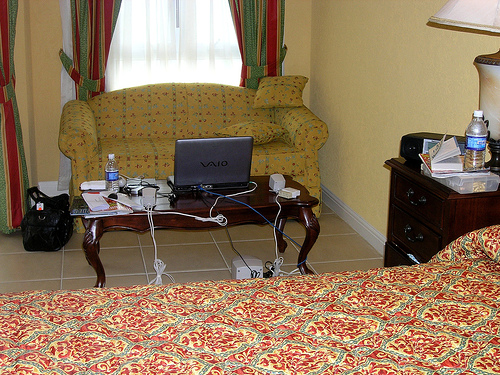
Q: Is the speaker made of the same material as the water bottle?
A: Yes, both the speaker and the water bottle are made of plastic.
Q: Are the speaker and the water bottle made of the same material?
A: Yes, both the speaker and the water bottle are made of plastic.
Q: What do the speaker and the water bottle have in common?
A: The material, both the speaker and the water bottle are plastic.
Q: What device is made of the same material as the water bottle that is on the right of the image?
A: The speaker is made of the same material as the water bottle.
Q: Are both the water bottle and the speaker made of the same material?
A: Yes, both the water bottle and the speaker are made of plastic.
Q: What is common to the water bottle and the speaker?
A: The material, both the water bottle and the speaker are plastic.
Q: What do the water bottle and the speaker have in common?
A: The material, both the water bottle and the speaker are plastic.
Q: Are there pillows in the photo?
A: Yes, there is a pillow.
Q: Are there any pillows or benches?
A: Yes, there is a pillow.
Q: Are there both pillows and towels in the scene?
A: No, there is a pillow but no towels.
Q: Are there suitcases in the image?
A: No, there are no suitcases.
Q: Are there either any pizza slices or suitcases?
A: No, there are no suitcases or pizza slices.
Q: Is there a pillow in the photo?
A: Yes, there is a pillow.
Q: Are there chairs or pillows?
A: Yes, there is a pillow.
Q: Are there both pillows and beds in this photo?
A: Yes, there are both a pillow and a bed.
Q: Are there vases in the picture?
A: No, there are no vases.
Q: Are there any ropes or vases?
A: No, there are no vases or ropes.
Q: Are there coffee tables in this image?
A: Yes, there is a coffee table.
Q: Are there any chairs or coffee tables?
A: Yes, there is a coffee table.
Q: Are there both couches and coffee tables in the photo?
A: Yes, there are both a coffee table and a couch.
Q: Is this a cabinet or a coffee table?
A: This is a coffee table.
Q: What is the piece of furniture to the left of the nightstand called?
A: The piece of furniture is a coffee table.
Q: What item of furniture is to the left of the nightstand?
A: The piece of furniture is a coffee table.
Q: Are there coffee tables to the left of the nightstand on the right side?
A: Yes, there is a coffee table to the left of the nightstand.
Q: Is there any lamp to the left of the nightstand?
A: No, there is a coffee table to the left of the nightstand.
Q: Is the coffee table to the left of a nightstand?
A: Yes, the coffee table is to the left of a nightstand.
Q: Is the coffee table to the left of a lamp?
A: No, the coffee table is to the left of a nightstand.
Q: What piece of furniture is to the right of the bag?
A: The piece of furniture is a coffee table.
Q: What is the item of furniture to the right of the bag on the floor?
A: The piece of furniture is a coffee table.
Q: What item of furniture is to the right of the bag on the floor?
A: The piece of furniture is a coffee table.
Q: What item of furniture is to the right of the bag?
A: The piece of furniture is a coffee table.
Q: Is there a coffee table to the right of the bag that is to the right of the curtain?
A: Yes, there is a coffee table to the right of the bag.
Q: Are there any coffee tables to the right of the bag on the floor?
A: Yes, there is a coffee table to the right of the bag.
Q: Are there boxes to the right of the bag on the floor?
A: No, there is a coffee table to the right of the bag.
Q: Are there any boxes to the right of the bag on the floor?
A: No, there is a coffee table to the right of the bag.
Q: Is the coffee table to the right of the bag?
A: Yes, the coffee table is to the right of the bag.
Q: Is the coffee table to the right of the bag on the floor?
A: Yes, the coffee table is to the right of the bag.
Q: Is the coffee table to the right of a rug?
A: No, the coffee table is to the right of the bag.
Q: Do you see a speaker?
A: Yes, there is a speaker.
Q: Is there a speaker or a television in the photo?
A: Yes, there is a speaker.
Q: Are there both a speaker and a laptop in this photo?
A: Yes, there are both a speaker and a laptop.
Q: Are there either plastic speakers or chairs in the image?
A: Yes, there is a plastic speaker.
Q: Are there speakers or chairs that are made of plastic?
A: Yes, the speaker is made of plastic.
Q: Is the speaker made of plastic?
A: Yes, the speaker is made of plastic.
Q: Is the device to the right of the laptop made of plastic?
A: Yes, the speaker is made of plastic.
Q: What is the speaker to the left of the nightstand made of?
A: The speaker is made of plastic.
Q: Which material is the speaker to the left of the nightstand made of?
A: The speaker is made of plastic.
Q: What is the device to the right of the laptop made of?
A: The speaker is made of plastic.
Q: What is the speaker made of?
A: The speaker is made of plastic.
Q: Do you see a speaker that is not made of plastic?
A: No, there is a speaker but it is made of plastic.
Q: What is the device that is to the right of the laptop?
A: The device is a speaker.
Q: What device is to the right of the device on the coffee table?
A: The device is a speaker.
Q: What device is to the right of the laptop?
A: The device is a speaker.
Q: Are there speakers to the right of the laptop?
A: Yes, there is a speaker to the right of the laptop.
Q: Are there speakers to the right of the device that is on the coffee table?
A: Yes, there is a speaker to the right of the laptop.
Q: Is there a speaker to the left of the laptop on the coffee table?
A: No, the speaker is to the right of the laptop.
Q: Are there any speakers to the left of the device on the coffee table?
A: No, the speaker is to the right of the laptop.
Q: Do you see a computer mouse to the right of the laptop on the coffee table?
A: No, there is a speaker to the right of the laptop.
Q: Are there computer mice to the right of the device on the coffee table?
A: No, there is a speaker to the right of the laptop.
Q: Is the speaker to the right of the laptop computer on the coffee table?
A: Yes, the speaker is to the right of the laptop computer.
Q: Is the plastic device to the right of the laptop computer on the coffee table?
A: Yes, the speaker is to the right of the laptop computer.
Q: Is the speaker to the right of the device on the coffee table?
A: Yes, the speaker is to the right of the laptop computer.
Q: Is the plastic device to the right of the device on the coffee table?
A: Yes, the speaker is to the right of the laptop computer.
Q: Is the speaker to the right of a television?
A: No, the speaker is to the right of the laptop computer.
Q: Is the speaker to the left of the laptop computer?
A: No, the speaker is to the right of the laptop computer.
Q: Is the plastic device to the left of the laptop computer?
A: No, the speaker is to the right of the laptop computer.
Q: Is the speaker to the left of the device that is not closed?
A: No, the speaker is to the right of the laptop computer.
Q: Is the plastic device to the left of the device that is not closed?
A: No, the speaker is to the right of the laptop computer.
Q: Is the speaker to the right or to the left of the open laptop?
A: The speaker is to the right of the laptop computer.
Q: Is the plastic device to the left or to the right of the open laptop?
A: The speaker is to the right of the laptop computer.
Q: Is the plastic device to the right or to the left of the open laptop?
A: The speaker is to the right of the laptop computer.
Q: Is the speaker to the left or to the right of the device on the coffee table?
A: The speaker is to the right of the laptop computer.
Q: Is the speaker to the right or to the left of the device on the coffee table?
A: The speaker is to the right of the laptop computer.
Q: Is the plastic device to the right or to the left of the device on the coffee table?
A: The speaker is to the right of the laptop computer.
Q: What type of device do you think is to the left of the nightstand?
A: The device is a speaker.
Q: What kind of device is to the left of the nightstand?
A: The device is a speaker.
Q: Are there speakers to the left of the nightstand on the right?
A: Yes, there is a speaker to the left of the nightstand.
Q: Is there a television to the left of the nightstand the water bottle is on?
A: No, there is a speaker to the left of the nightstand.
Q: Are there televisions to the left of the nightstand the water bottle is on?
A: No, there is a speaker to the left of the nightstand.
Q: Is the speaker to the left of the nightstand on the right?
A: Yes, the speaker is to the left of the nightstand.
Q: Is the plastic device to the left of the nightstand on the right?
A: Yes, the speaker is to the left of the nightstand.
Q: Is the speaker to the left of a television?
A: No, the speaker is to the left of the nightstand.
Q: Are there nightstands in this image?
A: Yes, there is a nightstand.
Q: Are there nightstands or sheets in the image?
A: Yes, there is a nightstand.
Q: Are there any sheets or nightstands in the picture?
A: Yes, there is a nightstand.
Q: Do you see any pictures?
A: No, there are no pictures.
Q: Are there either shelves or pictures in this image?
A: No, there are no pictures or shelves.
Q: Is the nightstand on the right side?
A: Yes, the nightstand is on the right of the image.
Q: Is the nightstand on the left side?
A: No, the nightstand is on the right of the image.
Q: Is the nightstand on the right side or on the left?
A: The nightstand is on the right of the image.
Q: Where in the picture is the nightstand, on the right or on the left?
A: The nightstand is on the right of the image.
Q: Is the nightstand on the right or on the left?
A: The nightstand is on the right of the image.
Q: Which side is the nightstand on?
A: The nightstand is on the right of the image.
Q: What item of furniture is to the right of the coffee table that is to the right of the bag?
A: The piece of furniture is a nightstand.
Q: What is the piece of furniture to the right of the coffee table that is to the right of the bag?
A: The piece of furniture is a nightstand.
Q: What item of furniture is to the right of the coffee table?
A: The piece of furniture is a nightstand.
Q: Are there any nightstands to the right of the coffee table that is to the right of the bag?
A: Yes, there is a nightstand to the right of the coffee table.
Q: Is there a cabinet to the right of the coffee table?
A: No, there is a nightstand to the right of the coffee table.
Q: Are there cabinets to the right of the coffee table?
A: No, there is a nightstand to the right of the coffee table.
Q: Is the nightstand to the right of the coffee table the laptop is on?
A: Yes, the nightstand is to the right of the coffee table.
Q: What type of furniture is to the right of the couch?
A: The piece of furniture is a nightstand.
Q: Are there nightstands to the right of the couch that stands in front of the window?
A: Yes, there is a nightstand to the right of the couch.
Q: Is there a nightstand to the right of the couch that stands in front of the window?
A: Yes, there is a nightstand to the right of the couch.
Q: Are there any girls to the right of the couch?
A: No, there is a nightstand to the right of the couch.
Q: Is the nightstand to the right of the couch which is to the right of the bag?
A: Yes, the nightstand is to the right of the couch.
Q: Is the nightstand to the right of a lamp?
A: No, the nightstand is to the right of the couch.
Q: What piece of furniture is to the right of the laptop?
A: The piece of furniture is a nightstand.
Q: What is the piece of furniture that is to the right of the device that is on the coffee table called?
A: The piece of furniture is a nightstand.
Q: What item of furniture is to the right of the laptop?
A: The piece of furniture is a nightstand.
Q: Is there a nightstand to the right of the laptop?
A: Yes, there is a nightstand to the right of the laptop.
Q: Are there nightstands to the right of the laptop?
A: Yes, there is a nightstand to the right of the laptop.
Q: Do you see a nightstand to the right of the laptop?
A: Yes, there is a nightstand to the right of the laptop.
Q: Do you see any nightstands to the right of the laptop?
A: Yes, there is a nightstand to the right of the laptop.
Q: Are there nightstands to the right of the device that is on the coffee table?
A: Yes, there is a nightstand to the right of the laptop.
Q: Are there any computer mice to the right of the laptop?
A: No, there is a nightstand to the right of the laptop.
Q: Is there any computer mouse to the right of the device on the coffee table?
A: No, there is a nightstand to the right of the laptop.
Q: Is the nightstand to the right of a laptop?
A: Yes, the nightstand is to the right of a laptop.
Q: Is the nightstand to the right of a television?
A: No, the nightstand is to the right of a laptop.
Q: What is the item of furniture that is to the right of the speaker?
A: The piece of furniture is a nightstand.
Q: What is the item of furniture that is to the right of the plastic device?
A: The piece of furniture is a nightstand.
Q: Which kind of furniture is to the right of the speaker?
A: The piece of furniture is a nightstand.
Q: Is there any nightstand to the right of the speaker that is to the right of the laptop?
A: Yes, there is a nightstand to the right of the speaker.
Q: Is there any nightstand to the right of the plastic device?
A: Yes, there is a nightstand to the right of the speaker.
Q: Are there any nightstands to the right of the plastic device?
A: Yes, there is a nightstand to the right of the speaker.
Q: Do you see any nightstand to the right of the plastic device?
A: Yes, there is a nightstand to the right of the speaker.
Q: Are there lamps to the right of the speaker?
A: No, there is a nightstand to the right of the speaker.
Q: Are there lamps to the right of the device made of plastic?
A: No, there is a nightstand to the right of the speaker.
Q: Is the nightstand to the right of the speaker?
A: Yes, the nightstand is to the right of the speaker.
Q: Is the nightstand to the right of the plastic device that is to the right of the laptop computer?
A: Yes, the nightstand is to the right of the speaker.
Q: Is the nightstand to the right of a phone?
A: No, the nightstand is to the right of the speaker.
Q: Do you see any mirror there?
A: No, there are no mirrors.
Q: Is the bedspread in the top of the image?
A: No, the bedspread is in the bottom of the image.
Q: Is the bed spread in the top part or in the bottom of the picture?
A: The bed spread is in the bottom of the image.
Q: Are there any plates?
A: No, there are no plates.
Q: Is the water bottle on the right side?
A: Yes, the water bottle is on the right of the image.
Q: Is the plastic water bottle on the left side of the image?
A: No, the water bottle is on the right of the image.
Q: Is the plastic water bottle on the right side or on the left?
A: The water bottle is on the right of the image.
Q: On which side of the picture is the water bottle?
A: The water bottle is on the right of the image.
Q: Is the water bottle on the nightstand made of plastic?
A: Yes, the water bottle is made of plastic.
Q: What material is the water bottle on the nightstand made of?
A: The water bottle is made of plastic.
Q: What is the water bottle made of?
A: The water bottle is made of plastic.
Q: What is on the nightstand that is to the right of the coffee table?
A: The water bottle is on the nightstand.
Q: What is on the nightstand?
A: The water bottle is on the nightstand.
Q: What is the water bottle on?
A: The water bottle is on the nightstand.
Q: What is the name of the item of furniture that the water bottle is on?
A: The piece of furniture is a nightstand.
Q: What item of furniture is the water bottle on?
A: The water bottle is on the nightstand.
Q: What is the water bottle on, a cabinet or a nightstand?
A: The water bottle is on a nightstand.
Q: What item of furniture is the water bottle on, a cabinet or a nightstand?
A: The water bottle is on a nightstand.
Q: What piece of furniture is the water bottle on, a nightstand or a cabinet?
A: The water bottle is on a nightstand.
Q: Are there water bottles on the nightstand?
A: Yes, there is a water bottle on the nightstand.